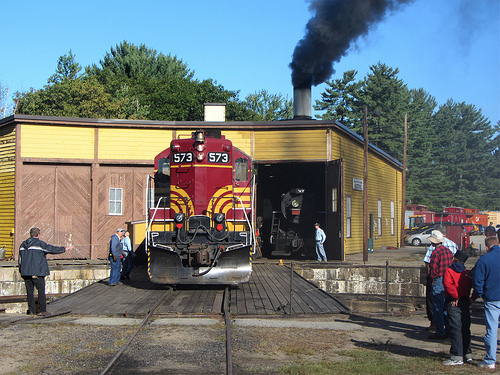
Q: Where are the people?
A: Beside the train tracks.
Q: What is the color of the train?
A: Red.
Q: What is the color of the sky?
A: Blue.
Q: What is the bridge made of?
A: Wood.